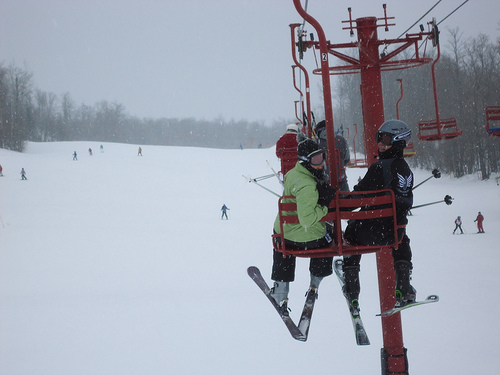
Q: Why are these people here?
A: To ski.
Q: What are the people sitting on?
A: Ski lift.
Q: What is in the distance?
A: Trees.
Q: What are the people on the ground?
A: Doing.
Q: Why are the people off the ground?
A: They are in a ski lift.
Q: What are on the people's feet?
A: Skis.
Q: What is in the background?
A: Trees.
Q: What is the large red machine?
A: Ski lift.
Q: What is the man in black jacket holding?
A: Ski poles.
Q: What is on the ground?
A: Snow.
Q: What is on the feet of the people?
A: Skis.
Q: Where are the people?
A: On a ski hill.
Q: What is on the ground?
A: Snow.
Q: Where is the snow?
A: On the ground.